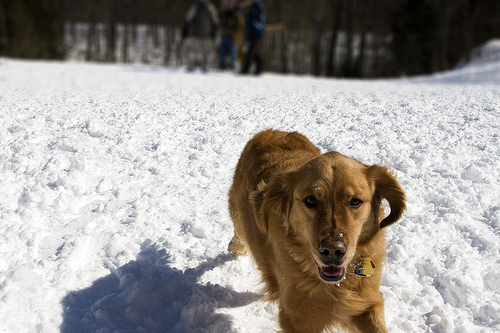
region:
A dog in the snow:
[228, 117, 383, 328]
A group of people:
[176, 0, 276, 80]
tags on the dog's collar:
[331, 240, 387, 295]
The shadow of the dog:
[75, 235, 220, 327]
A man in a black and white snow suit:
[170, 5, 225, 75]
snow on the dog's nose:
[320, 217, 361, 237]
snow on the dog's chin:
[330, 270, 345, 285]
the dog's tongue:
[305, 256, 347, 272]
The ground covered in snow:
[10, 55, 495, 320]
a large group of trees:
[46, 10, 397, 73]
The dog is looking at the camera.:
[216, 140, 423, 321]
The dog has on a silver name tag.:
[343, 251, 386, 284]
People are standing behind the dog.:
[154, 13, 323, 99]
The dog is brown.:
[208, 123, 425, 332]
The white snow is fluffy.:
[32, 86, 188, 228]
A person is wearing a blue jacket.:
[236, 10, 281, 34]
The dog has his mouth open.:
[309, 232, 375, 294]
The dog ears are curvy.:
[240, 159, 414, 232]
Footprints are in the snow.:
[41, 161, 177, 248]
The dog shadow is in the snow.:
[63, 237, 245, 323]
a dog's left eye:
[333, 186, 379, 221]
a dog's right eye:
[298, 185, 327, 217]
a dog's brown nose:
[315, 234, 348, 261]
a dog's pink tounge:
[317, 257, 345, 280]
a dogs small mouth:
[306, 239, 355, 288]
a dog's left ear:
[378, 148, 415, 233]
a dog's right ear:
[256, 152, 301, 247]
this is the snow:
[107, 147, 159, 172]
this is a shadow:
[48, 222, 261, 330]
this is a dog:
[99, 114, 416, 331]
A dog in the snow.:
[187, 95, 463, 330]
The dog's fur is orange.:
[190, 110, 448, 331]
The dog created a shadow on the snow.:
[15, 211, 253, 331]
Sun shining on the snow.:
[13, 86, 176, 188]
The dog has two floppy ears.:
[245, 163, 416, 238]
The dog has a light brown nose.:
[313, 231, 348, 263]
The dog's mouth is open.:
[305, 255, 351, 290]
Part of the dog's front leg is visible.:
[345, 296, 400, 331]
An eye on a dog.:
[345, 186, 366, 217]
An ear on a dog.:
[358, 157, 419, 240]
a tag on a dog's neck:
[351, 255, 377, 277]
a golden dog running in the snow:
[222, 126, 407, 327]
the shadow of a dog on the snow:
[47, 221, 257, 326]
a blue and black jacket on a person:
[240, 0, 265, 35]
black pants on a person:
[242, 36, 268, 77]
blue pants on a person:
[215, 30, 235, 70]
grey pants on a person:
[185, 30, 220, 72]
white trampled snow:
[0, 60, 492, 330]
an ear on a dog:
[369, 163, 412, 228]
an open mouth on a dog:
[310, 259, 351, 284]